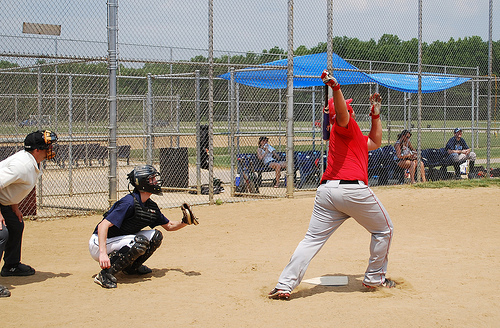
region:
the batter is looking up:
[243, 30, 452, 327]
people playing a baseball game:
[23, 28, 478, 288]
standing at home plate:
[263, 148, 406, 305]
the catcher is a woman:
[53, 95, 230, 292]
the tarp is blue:
[208, 40, 494, 150]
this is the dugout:
[225, 41, 495, 180]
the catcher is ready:
[12, 28, 434, 308]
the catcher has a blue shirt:
[81, 135, 223, 305]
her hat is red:
[268, 33, 433, 313]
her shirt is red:
[270, 46, 472, 301]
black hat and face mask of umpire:
[20, 125, 57, 157]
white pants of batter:
[276, 176, 387, 287]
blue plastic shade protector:
[220, 42, 490, 103]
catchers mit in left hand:
[172, 190, 200, 230]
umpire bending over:
[0, 123, 66, 298]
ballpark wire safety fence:
[5, 40, 495, 200]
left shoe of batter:
[262, 280, 293, 298]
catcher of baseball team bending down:
[81, 155, 201, 290]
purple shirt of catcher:
[83, 186, 176, 241]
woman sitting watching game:
[252, 130, 293, 191]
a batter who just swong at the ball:
[263, 58, 414, 300]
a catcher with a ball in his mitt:
[95, 141, 224, 283]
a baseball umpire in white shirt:
[3, 114, 60, 274]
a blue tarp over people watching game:
[231, 34, 491, 204]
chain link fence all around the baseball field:
[9, 6, 496, 216]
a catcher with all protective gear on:
[93, 152, 192, 297]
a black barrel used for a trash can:
[153, 140, 192, 203]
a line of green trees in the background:
[24, 35, 492, 138]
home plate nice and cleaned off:
[301, 264, 353, 305]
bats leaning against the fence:
[232, 149, 274, 197]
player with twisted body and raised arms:
[258, 63, 413, 305]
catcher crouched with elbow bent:
[82, 142, 203, 297]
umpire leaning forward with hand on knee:
[5, 91, 66, 291]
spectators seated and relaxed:
[240, 121, 481, 166]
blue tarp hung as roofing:
[220, 36, 470, 101]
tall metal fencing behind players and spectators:
[40, 15, 490, 205]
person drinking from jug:
[247, 112, 287, 192]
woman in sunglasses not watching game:
[390, 112, 435, 192]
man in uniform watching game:
[440, 117, 485, 178]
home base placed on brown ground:
[201, 225, 451, 311]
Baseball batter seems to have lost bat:
[266, 67, 392, 302]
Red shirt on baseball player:
[320, 110, 370, 185]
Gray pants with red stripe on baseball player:
[275, 180, 395, 297]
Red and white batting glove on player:
[366, 90, 386, 117]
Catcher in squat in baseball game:
[85, 160, 196, 290]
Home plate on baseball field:
[300, 266, 355, 288]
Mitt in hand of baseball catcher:
[176, 196, 200, 227]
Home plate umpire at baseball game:
[0, 125, 57, 295]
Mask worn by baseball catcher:
[125, 161, 162, 196]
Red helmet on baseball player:
[323, 89, 356, 121]